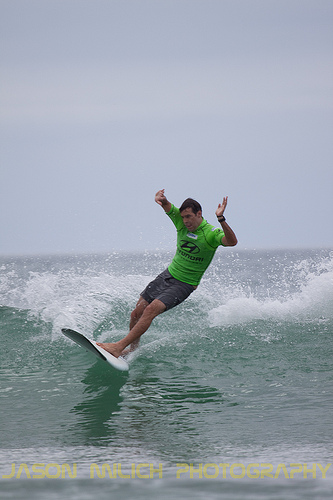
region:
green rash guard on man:
[166, 186, 247, 285]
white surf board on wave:
[44, 320, 135, 389]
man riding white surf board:
[38, 180, 233, 397]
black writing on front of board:
[181, 236, 196, 270]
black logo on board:
[176, 239, 204, 258]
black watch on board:
[216, 209, 228, 227]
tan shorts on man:
[140, 264, 195, 310]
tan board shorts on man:
[143, 264, 195, 309]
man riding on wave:
[55, 185, 231, 369]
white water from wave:
[209, 269, 319, 323]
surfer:
[50, 182, 245, 375]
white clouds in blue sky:
[45, 7, 88, 46]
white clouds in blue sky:
[259, 122, 317, 183]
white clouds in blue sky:
[116, 66, 177, 115]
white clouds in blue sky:
[74, 129, 99, 153]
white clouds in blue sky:
[236, 102, 299, 157]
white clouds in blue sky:
[86, 89, 121, 124]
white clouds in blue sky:
[180, 19, 225, 53]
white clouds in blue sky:
[109, 37, 143, 66]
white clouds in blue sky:
[40, 28, 107, 99]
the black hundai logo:
[166, 239, 211, 267]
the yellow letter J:
[0, 459, 21, 484]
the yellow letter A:
[12, 455, 31, 484]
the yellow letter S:
[25, 456, 51, 484]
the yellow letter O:
[42, 459, 62, 481]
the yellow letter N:
[56, 457, 79, 480]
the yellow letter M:
[89, 455, 111, 486]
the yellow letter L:
[109, 453, 136, 481]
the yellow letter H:
[146, 452, 164, 487]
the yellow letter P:
[172, 453, 193, 479]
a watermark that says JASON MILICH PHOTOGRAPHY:
[0, 460, 329, 477]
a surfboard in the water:
[58, 319, 142, 366]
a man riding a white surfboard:
[54, 180, 243, 367]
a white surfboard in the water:
[56, 320, 157, 375]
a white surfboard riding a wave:
[58, 321, 150, 377]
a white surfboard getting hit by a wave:
[57, 326, 164, 375]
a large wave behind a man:
[4, 248, 332, 373]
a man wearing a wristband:
[216, 214, 225, 221]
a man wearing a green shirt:
[161, 202, 227, 288]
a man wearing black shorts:
[136, 266, 198, 311]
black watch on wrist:
[216, 212, 228, 221]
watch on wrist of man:
[217, 212, 231, 223]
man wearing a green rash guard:
[160, 197, 232, 283]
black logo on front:
[179, 237, 198, 255]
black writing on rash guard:
[163, 237, 207, 269]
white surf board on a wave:
[61, 327, 136, 375]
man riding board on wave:
[53, 167, 242, 407]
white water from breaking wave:
[247, 264, 325, 323]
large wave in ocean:
[4, 309, 310, 454]